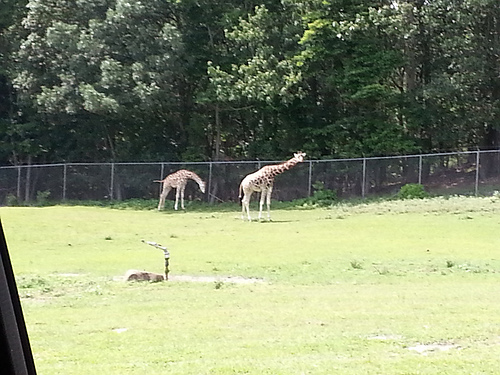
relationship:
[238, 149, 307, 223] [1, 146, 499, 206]
giraffe against fence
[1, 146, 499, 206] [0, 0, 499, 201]
fence in front of trees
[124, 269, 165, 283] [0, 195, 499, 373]
rock in grass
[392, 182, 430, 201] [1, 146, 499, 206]
bush in front of fence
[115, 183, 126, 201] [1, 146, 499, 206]
tree trunk behind fence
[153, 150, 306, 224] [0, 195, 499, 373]
giraffes in grass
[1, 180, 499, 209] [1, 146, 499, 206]
shrubs near fence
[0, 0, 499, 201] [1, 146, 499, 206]
trees above fence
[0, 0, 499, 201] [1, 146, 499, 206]
trees behind fence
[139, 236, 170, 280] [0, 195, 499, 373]
pipe in grass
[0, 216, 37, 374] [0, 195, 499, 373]
window edge in front of grass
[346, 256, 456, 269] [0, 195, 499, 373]
tufts in grass